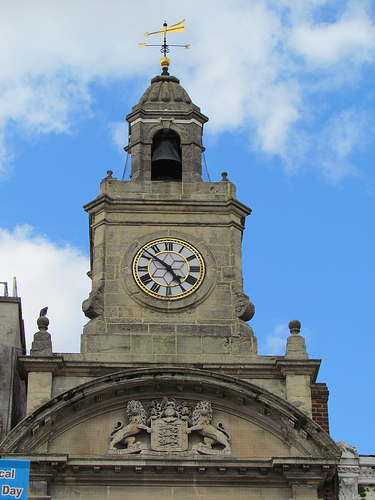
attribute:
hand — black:
[170, 271, 182, 292]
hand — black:
[141, 242, 173, 264]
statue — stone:
[185, 399, 233, 457]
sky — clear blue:
[238, 84, 347, 168]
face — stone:
[199, 402, 209, 414]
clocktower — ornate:
[80, 180, 273, 364]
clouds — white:
[5, 74, 79, 280]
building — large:
[51, 5, 359, 492]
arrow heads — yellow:
[137, 30, 149, 47]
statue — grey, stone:
[144, 393, 194, 455]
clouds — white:
[231, 32, 352, 186]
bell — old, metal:
[151, 137, 182, 167]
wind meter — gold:
[137, 19, 189, 69]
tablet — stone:
[142, 406, 190, 452]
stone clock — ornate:
[84, 72, 265, 287]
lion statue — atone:
[109, 396, 152, 454]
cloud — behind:
[294, 30, 338, 63]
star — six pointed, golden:
[146, 254, 187, 292]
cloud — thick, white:
[2, 225, 95, 355]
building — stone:
[43, 29, 291, 497]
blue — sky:
[282, 158, 345, 273]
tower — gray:
[77, 52, 257, 356]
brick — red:
[314, 383, 326, 430]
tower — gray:
[79, 25, 257, 351]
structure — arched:
[6, 363, 338, 453]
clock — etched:
[131, 234, 206, 303]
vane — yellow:
[136, 16, 193, 56]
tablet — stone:
[146, 396, 191, 454]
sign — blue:
[2, 458, 29, 494]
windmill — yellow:
[139, 15, 190, 77]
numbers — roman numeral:
[137, 241, 201, 299]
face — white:
[132, 237, 200, 297]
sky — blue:
[3, 29, 363, 447]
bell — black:
[146, 135, 186, 172]